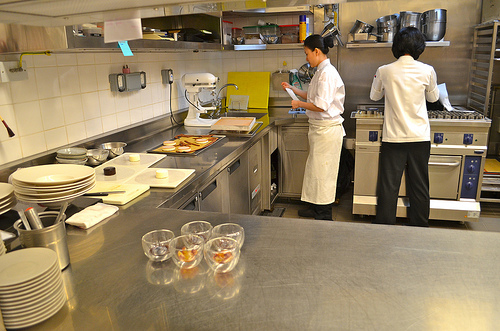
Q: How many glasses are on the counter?
A: 5.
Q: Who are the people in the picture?
A: Chefs.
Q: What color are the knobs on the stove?
A: Blue.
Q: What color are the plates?
A: White.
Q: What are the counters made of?
A: Stainless steel.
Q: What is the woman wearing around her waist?
A: Apron.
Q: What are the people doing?
A: Cooking.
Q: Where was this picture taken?
A: Kitchen.